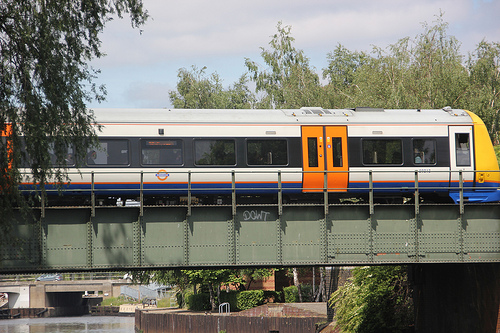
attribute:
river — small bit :
[6, 315, 95, 331]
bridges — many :
[1, 205, 498, 265]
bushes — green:
[172, 283, 304, 314]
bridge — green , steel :
[7, 209, 498, 266]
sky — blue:
[0, 2, 497, 108]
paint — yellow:
[467, 110, 499, 180]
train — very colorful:
[2, 103, 498, 207]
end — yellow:
[466, 111, 498, 194]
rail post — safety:
[322, 170, 330, 215]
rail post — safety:
[178, 164, 444, 244]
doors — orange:
[287, 110, 362, 219]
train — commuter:
[15, 101, 465, 238]